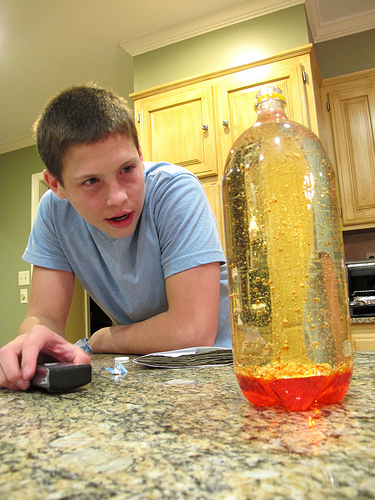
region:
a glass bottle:
[222, 90, 353, 401]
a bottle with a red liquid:
[222, 98, 355, 404]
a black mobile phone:
[42, 359, 95, 392]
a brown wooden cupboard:
[182, 87, 235, 130]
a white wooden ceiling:
[23, 21, 105, 52]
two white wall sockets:
[20, 272, 29, 302]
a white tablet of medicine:
[113, 355, 132, 363]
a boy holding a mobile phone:
[2, 84, 147, 405]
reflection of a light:
[225, 48, 280, 84]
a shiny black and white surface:
[88, 429, 235, 493]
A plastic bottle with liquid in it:
[216, 77, 354, 411]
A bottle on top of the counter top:
[219, 73, 366, 472]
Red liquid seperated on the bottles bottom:
[225, 358, 352, 409]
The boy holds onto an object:
[0, 324, 99, 402]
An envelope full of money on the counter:
[124, 345, 237, 372]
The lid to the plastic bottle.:
[109, 351, 132, 365]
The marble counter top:
[0, 411, 231, 498]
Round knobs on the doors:
[199, 116, 231, 135]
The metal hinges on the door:
[298, 66, 309, 84]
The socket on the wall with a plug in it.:
[366, 248, 374, 262]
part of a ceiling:
[91, 14, 123, 39]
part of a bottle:
[290, 397, 308, 420]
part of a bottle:
[283, 383, 317, 435]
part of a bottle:
[278, 365, 309, 425]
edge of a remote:
[55, 366, 80, 394]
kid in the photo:
[28, 79, 199, 261]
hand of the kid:
[0, 317, 94, 408]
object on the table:
[41, 353, 84, 401]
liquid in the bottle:
[258, 345, 351, 418]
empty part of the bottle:
[216, 157, 351, 297]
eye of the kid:
[115, 153, 139, 188]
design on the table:
[137, 397, 214, 473]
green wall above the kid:
[187, 30, 252, 58]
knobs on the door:
[187, 111, 237, 139]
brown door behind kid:
[157, 100, 201, 143]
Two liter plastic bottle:
[217, 81, 355, 413]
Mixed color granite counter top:
[0, 349, 373, 497]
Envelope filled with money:
[130, 345, 232, 372]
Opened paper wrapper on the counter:
[98, 362, 130, 380]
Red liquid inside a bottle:
[227, 365, 364, 415]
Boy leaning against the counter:
[1, 81, 232, 392]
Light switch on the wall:
[16, 268, 29, 287]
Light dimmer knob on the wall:
[17, 286, 27, 304]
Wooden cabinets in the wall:
[123, 40, 374, 243]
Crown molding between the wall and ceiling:
[113, 1, 373, 67]